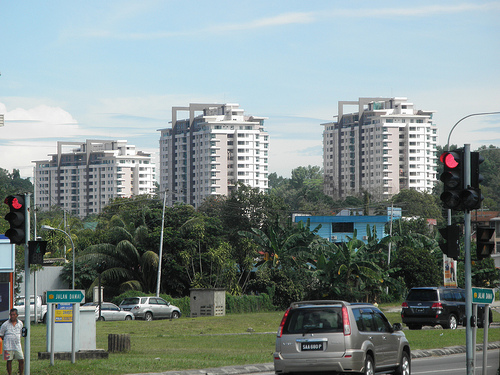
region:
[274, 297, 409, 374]
a vehicle on the road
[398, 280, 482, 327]
a vehicle on the road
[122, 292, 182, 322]
a vehicle on the road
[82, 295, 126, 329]
a vehicle on the road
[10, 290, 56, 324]
a vehicle on the road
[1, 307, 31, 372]
a person is standing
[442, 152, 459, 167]
a red traffic light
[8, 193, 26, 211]
a red traffic light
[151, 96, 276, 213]
a large white building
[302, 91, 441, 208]
a large white building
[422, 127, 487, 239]
stoplight with red light lit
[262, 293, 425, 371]
gray SUV with darkened windows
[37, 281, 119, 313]
green directional street sign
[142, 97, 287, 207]
multi-storied white building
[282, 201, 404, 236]
blue stucco structure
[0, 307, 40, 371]
man in white shirt and shorts waiting to cross street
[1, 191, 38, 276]
stoplight with red light shining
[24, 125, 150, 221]
large white building with balconies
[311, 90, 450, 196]
large white building with windows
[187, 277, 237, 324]
gray transformer box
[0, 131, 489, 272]
two traffic lights on poles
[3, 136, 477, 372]
two grey poles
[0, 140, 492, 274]
black traffic light casings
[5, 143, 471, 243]
two red lights in black casing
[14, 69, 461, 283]
three white buildings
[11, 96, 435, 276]
a whole bunch of windows on the buildings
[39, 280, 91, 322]
a green direction sign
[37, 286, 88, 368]
a sign on two posts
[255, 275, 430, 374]
a tan car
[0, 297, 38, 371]
a person under the traffic light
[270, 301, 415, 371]
A ligh colored mid-size SUV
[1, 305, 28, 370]
A man wearing a shirt and shorts standing on the side of the road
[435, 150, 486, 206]
A red stop light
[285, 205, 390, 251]
A blue building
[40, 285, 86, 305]
Green street sign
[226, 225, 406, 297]
Palm trees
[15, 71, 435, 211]
Three tall buildings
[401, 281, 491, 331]
Dark colored SUV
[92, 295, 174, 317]
Two silver cars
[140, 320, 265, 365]
Green grass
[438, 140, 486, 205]
red stop light.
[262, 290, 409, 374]
car on the road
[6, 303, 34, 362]
person beside the street.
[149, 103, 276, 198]
tall building in the sky.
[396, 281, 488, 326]
black car on street.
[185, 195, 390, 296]
trees on the ground.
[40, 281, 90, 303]
sign pointing to the direction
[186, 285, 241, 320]
grey box on the grass.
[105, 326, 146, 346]
piece of wood on ground.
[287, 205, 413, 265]
blue building behind tree.